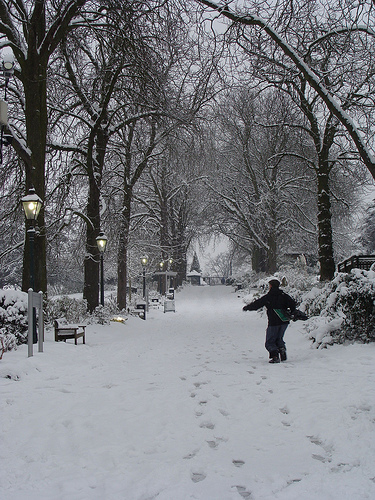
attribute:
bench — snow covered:
[45, 304, 97, 356]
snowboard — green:
[272, 304, 306, 326]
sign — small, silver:
[24, 283, 48, 359]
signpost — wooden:
[24, 282, 48, 360]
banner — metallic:
[25, 286, 45, 359]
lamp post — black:
[19, 192, 45, 291]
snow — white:
[1, 283, 372, 498]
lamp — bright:
[22, 187, 40, 222]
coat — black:
[236, 286, 310, 329]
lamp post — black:
[139, 252, 149, 300]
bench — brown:
[53, 317, 85, 344]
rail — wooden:
[336, 252, 373, 269]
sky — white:
[1, 4, 374, 263]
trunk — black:
[317, 176, 335, 279]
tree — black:
[232, 3, 373, 279]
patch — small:
[88, 337, 246, 474]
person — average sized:
[243, 277, 300, 364]